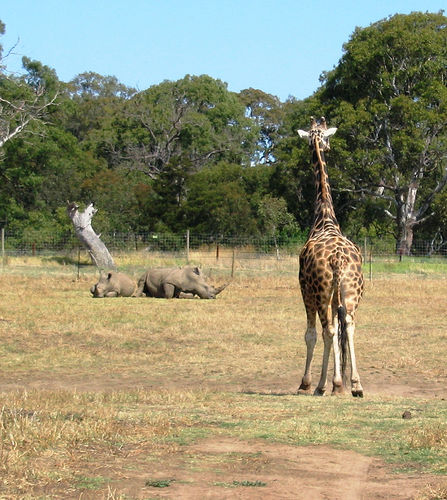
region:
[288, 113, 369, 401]
a giraffe in a field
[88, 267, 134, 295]
a rhino laying down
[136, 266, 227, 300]
a rhino laying down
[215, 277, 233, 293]
horn of a rhino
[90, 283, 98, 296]
horn of a rhino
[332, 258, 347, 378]
a giraffe's tail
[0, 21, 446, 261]
trees and brush behind a fence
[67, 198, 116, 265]
a dead tree trunk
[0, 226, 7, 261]
small wooden post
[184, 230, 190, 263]
small wooden post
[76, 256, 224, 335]
Hippos in the field.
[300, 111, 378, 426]
A giraffe in the field.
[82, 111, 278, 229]
Green trees behind the fence.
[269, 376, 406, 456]
Grass in the field.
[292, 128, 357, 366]
The giraffe is bron and white.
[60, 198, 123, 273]
A bare tree trunk behind the fence.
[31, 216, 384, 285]
A fence around the field.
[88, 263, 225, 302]
The rhino is laying in the grass.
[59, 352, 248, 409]
Dirt in the field.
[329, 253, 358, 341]
The tail of the giraffe is long.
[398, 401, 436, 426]
tan stone on the grass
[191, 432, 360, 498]
bald spot on the grass area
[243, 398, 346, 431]
parched green grass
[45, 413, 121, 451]
parched yellow grass on the ground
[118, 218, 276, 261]
large fence in the background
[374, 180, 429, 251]
wide tree trunk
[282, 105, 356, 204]
elongated neck on the giraffe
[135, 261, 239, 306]
hippo kneeling on the grass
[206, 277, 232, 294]
sharp horn on the hippo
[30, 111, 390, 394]
animals in an enclosure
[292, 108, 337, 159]
the head of a horned giraffe.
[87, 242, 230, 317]
A cluster of horned animal.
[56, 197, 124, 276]
A tree trunk in the ground.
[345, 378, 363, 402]
the right rear hoof of a giraffe.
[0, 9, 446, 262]
a forest filled with trees.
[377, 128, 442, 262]
a tree with lots of leaves.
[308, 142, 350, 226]
the long neck of a giraffe.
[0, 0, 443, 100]
a clear blue sky.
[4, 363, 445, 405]
a patch of dirt in a field.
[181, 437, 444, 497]
a patch of dirt near grass.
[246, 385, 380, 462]
grass patch on dirt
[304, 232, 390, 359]
tail of a giraffe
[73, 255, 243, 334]
two rhinos laying down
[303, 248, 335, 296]
yellow and brown on giraffe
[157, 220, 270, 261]
fence behind animals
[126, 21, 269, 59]
clear sky in background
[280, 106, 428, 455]
a giraffe standing in grass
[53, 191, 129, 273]
a tree stump behind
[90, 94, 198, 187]
big trees in the background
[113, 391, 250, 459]
yellow and green grass